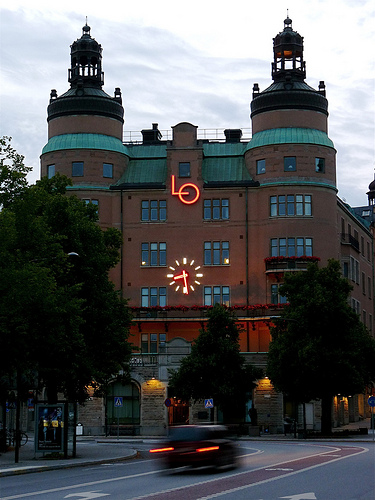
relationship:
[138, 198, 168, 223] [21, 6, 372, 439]
window on building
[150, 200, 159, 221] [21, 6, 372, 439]
window on building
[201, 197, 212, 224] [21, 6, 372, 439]
window on building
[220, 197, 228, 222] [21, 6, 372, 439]
window on building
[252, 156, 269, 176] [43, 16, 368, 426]
window on building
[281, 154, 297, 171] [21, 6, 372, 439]
window on building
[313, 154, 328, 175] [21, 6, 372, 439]
window on building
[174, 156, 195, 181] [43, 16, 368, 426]
window on building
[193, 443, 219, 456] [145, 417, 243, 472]
light on car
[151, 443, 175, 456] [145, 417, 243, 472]
light on car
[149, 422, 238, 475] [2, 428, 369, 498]
car on road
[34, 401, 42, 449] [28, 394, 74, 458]
border on poster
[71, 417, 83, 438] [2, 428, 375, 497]
trash can on road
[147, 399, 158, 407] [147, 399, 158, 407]
bricks are on bricks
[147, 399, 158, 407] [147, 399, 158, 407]
bricks has bricks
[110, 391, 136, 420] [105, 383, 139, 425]
drapes are in drapes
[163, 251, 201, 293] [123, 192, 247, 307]
clock on wall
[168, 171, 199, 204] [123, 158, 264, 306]
logo on wall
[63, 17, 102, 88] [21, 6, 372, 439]
steeple on top of building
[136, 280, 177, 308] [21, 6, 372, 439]
window on building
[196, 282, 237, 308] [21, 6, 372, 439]
window on building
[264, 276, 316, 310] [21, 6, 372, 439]
window on building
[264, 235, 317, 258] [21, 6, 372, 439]
window on building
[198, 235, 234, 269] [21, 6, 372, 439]
window on building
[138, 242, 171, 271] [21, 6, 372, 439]
window on building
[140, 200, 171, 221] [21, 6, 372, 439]
window of building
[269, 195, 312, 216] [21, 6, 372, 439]
window of building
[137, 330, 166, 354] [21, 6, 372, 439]
window of building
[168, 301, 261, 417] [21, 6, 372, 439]
tree in front of building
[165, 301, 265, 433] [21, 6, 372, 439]
tree in front of building